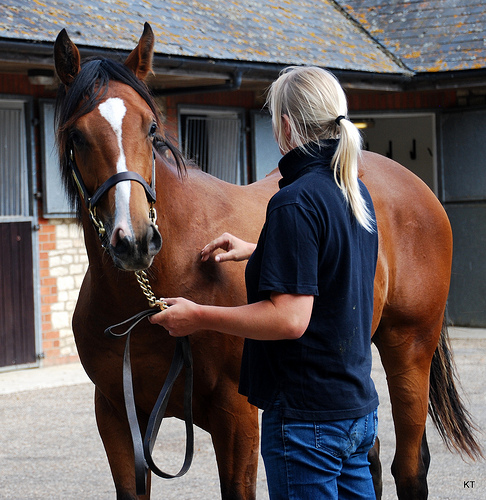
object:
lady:
[147, 66, 377, 498]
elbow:
[268, 308, 311, 343]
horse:
[50, 22, 479, 500]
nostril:
[142, 225, 164, 257]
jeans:
[257, 411, 378, 500]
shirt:
[236, 139, 380, 417]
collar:
[272, 138, 345, 183]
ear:
[126, 21, 155, 78]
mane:
[46, 49, 188, 204]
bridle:
[64, 101, 159, 253]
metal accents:
[85, 206, 106, 235]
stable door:
[0, 99, 43, 373]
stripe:
[92, 96, 146, 241]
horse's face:
[49, 21, 171, 273]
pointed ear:
[53, 27, 80, 88]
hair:
[268, 64, 371, 228]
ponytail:
[330, 116, 376, 234]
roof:
[2, 0, 414, 76]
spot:
[401, 48, 422, 60]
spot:
[263, 45, 272, 58]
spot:
[90, 13, 112, 21]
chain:
[133, 268, 169, 312]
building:
[2, 0, 486, 368]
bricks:
[47, 301, 63, 316]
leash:
[105, 272, 213, 496]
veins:
[397, 398, 415, 424]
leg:
[380, 294, 432, 499]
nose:
[109, 181, 161, 264]